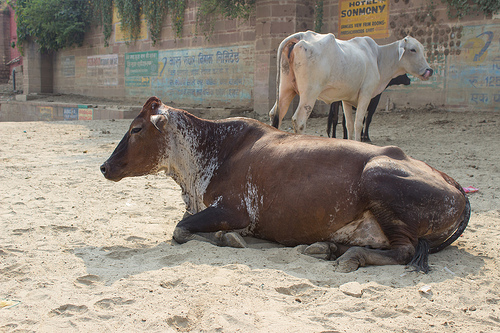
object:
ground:
[2, 82, 499, 326]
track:
[77, 272, 101, 291]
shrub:
[5, 1, 90, 48]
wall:
[54, 1, 498, 112]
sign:
[337, 0, 390, 40]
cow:
[101, 95, 472, 274]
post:
[12, 69, 17, 94]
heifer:
[266, 29, 433, 140]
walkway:
[5, 83, 249, 114]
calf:
[327, 75, 412, 143]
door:
[9, 9, 24, 76]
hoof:
[216, 230, 250, 247]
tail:
[404, 184, 473, 272]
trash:
[463, 184, 482, 195]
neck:
[164, 106, 215, 198]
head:
[99, 96, 179, 182]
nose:
[97, 160, 112, 179]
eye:
[129, 124, 143, 135]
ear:
[150, 113, 166, 131]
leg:
[172, 203, 247, 251]